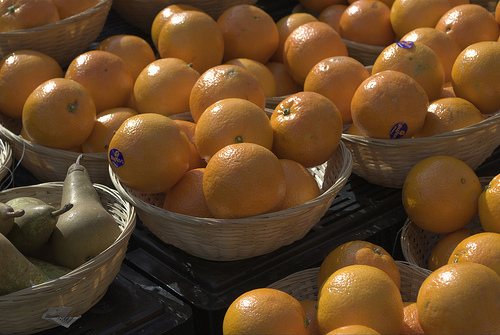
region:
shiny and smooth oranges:
[308, 252, 448, 329]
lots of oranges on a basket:
[94, 99, 366, 260]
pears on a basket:
[5, 158, 131, 330]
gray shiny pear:
[51, 155, 139, 306]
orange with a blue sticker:
[345, 57, 431, 154]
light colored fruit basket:
[329, 96, 495, 178]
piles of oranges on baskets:
[48, 2, 436, 223]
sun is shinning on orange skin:
[272, 9, 429, 153]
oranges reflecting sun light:
[405, 229, 487, 331]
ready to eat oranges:
[102, 38, 379, 250]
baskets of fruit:
[14, 2, 495, 311]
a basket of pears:
[8, 183, 144, 325]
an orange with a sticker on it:
[102, 111, 179, 200]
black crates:
[130, 269, 315, 324]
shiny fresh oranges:
[122, 96, 330, 226]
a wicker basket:
[165, 212, 311, 259]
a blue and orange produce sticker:
[110, 147, 129, 164]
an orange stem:
[55, 90, 85, 120]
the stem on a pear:
[45, 202, 72, 217]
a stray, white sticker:
[40, 307, 65, 332]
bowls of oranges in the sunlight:
[3, 11, 498, 326]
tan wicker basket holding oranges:
[138, 210, 345, 261]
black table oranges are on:
[152, 263, 304, 288]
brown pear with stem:
[57, 150, 124, 260]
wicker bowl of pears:
[0, 160, 138, 333]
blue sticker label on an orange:
[386, 119, 413, 141]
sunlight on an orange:
[144, 62, 163, 79]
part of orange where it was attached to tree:
[281, 106, 294, 117]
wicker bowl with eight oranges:
[109, 90, 356, 266]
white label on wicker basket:
[39, 298, 86, 332]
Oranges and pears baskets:
[0, 0, 499, 331]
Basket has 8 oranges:
[99, 52, 356, 268]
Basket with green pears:
[2, 156, 137, 328]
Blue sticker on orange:
[100, 140, 125, 175]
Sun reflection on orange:
[125, 50, 195, 105]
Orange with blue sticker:
[345, 65, 430, 147]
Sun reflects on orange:
[126, 53, 191, 108]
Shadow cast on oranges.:
[242, 230, 392, 301]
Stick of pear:
[43, 195, 74, 221]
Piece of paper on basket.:
[37, 296, 84, 327]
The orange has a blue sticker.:
[105, 137, 132, 162]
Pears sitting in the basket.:
[41, 166, 124, 292]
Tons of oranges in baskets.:
[127, 29, 449, 155]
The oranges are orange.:
[185, 114, 310, 190]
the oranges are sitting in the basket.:
[126, 95, 350, 247]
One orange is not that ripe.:
[402, 44, 461, 90]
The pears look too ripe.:
[4, 179, 99, 292]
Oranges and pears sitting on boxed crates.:
[1, 159, 334, 276]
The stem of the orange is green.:
[68, 98, 79, 115]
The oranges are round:
[206, 149, 320, 224]